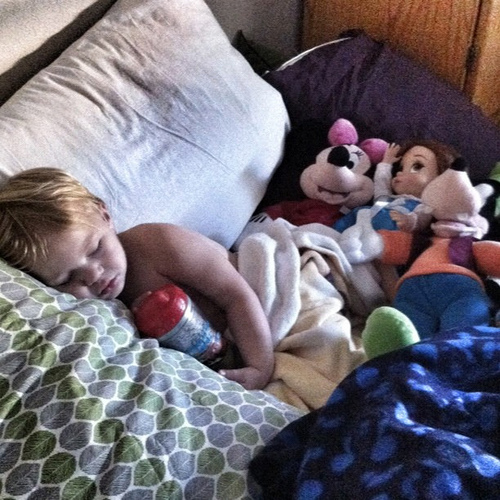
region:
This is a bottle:
[129, 278, 239, 371]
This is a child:
[2, 158, 333, 408]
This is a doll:
[313, 115, 368, 213]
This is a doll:
[377, 125, 435, 252]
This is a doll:
[434, 142, 494, 316]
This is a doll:
[302, 67, 391, 212]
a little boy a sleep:
[0, 165, 290, 375]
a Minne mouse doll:
[279, 124, 388, 224]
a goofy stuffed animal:
[348, 160, 493, 348]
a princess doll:
[334, 139, 448, 260]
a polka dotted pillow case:
[8, 334, 269, 487]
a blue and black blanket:
[251, 349, 483, 496]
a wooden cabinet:
[289, 6, 499, 100]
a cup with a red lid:
[132, 280, 239, 365]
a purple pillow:
[275, 36, 473, 143]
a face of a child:
[45, 221, 128, 298]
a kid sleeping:
[0, 177, 306, 382]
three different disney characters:
[299, 122, 489, 312]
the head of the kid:
[3, 178, 127, 302]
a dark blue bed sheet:
[278, 337, 489, 498]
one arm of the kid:
[207, 237, 272, 382]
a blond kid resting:
[4, 174, 274, 356]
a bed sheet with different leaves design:
[0, 352, 212, 493]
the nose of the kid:
[81, 267, 104, 287]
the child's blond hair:
[3, 172, 93, 250]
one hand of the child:
[220, 367, 270, 388]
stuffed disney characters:
[256, 119, 498, 356]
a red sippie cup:
[130, 285, 223, 360]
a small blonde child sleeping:
[0, 168, 276, 390]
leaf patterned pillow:
[0, 258, 310, 497]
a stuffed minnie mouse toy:
[249, 116, 389, 225]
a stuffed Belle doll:
[346, 133, 448, 223]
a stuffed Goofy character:
[339, 149, 499, 359]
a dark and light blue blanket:
[256, 329, 497, 498]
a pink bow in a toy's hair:
[329, 118, 390, 158]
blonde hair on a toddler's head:
[0, 166, 107, 258]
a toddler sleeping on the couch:
[5, 165, 277, 392]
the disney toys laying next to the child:
[271, 121, 493, 360]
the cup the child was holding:
[123, 280, 235, 362]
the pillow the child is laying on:
[3, 267, 279, 499]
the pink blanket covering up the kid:
[223, 221, 358, 411]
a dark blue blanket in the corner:
[264, 333, 486, 498]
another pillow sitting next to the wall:
[279, 23, 492, 183]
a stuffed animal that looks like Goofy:
[357, 164, 498, 326]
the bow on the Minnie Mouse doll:
[325, 115, 392, 162]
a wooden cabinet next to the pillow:
[301, 5, 498, 114]